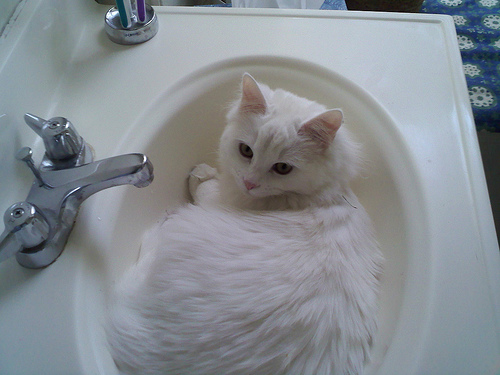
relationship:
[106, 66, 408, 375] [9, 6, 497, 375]
cat sitting in sink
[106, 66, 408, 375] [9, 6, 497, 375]
cat staying in sink sink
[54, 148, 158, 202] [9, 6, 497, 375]
faucet on sink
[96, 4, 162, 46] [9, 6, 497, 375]
holder sitting on sink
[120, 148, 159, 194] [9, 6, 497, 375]
spigot for sink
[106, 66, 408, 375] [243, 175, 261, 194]
cat has nose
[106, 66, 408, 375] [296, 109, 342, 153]
cat has ear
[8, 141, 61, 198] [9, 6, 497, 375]
stopper on a sink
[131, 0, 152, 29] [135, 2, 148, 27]
toothbrush has purple handle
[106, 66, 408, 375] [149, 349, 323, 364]
cat face camera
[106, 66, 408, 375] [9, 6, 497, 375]
cat in bathroom sink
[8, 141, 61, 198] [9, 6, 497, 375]
back splash on sink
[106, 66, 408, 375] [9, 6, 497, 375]
white kitty on sink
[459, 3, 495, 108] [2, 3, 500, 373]
mat in bathroom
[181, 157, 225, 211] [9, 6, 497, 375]
paw resting on sink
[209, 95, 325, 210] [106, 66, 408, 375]
face of cat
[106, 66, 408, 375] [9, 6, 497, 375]
cat in sink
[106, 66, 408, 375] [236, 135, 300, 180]
cat has eyes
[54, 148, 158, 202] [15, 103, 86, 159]
faucet has handle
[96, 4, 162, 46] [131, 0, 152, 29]
holder for toothbrush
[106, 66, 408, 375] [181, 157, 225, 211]
cat has paw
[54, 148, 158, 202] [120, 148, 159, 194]
faucet seen front part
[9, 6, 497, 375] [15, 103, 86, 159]
sink has knob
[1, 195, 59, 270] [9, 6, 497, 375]
knob on sink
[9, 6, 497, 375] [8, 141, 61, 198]
sink has stopper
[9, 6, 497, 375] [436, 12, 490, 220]
sink has edge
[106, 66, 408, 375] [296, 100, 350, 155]
cat seen ear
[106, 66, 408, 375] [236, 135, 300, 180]
cat seen eye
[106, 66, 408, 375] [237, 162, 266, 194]
cat seen nose